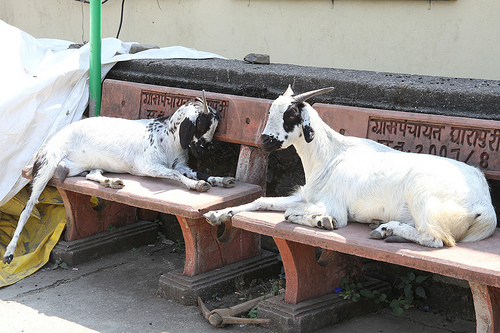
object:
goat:
[242, 88, 487, 283]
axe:
[185, 287, 296, 330]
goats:
[86, 84, 446, 237]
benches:
[120, 88, 404, 291]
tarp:
[3, 144, 75, 289]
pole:
[78, 30, 118, 112]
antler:
[285, 80, 343, 114]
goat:
[245, 76, 444, 297]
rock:
[208, 46, 284, 84]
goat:
[46, 99, 236, 249]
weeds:
[335, 264, 429, 330]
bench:
[185, 185, 471, 307]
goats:
[29, 87, 421, 256]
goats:
[236, 92, 456, 274]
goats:
[234, 79, 474, 272]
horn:
[286, 69, 354, 122]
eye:
[275, 90, 313, 128]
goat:
[244, 92, 462, 293]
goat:
[250, 106, 413, 232]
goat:
[293, 88, 483, 280]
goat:
[231, 101, 483, 294]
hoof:
[192, 196, 257, 226]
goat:
[233, 92, 478, 272]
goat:
[256, 90, 465, 245]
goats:
[46, 93, 411, 250]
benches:
[46, 106, 357, 286]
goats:
[44, 60, 464, 234]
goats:
[239, 103, 469, 258]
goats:
[0, 90, 267, 230]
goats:
[65, 82, 478, 255]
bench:
[139, 68, 412, 319]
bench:
[18, 71, 499, 329]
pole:
[86, 0, 107, 119]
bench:
[60, 75, 497, 331]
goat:
[201, 80, 498, 252]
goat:
[0, 89, 237, 272]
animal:
[196, 81, 499, 251]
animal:
[0, 91, 234, 271]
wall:
[3, 0, 497, 82]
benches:
[16, 74, 496, 330]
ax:
[183, 288, 271, 330]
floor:
[8, 228, 478, 330]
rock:
[237, 47, 274, 67]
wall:
[94, 43, 499, 120]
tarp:
[0, 10, 235, 217]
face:
[159, 99, 226, 166]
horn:
[275, 81, 297, 104]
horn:
[286, 83, 337, 104]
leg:
[199, 191, 287, 230]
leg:
[288, 200, 342, 235]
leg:
[367, 217, 445, 253]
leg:
[364, 219, 391, 245]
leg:
[0, 152, 64, 263]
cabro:
[0, 85, 240, 265]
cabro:
[198, 77, 499, 257]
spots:
[174, 117, 195, 150]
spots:
[192, 107, 212, 137]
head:
[159, 90, 228, 160]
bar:
[79, 3, 112, 121]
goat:
[253, 95, 477, 265]